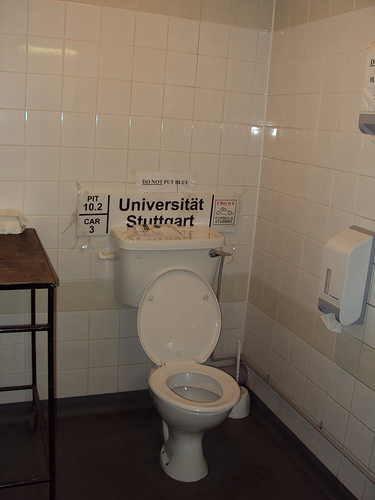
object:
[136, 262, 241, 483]
toilet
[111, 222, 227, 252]
sink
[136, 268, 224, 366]
lid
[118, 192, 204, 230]
writing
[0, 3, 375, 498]
wall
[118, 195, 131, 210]
word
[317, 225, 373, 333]
tissue dispesor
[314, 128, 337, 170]
tiles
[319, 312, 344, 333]
tissue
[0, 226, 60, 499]
table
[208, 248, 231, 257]
hadle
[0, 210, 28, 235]
paper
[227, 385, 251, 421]
bowl cleaner